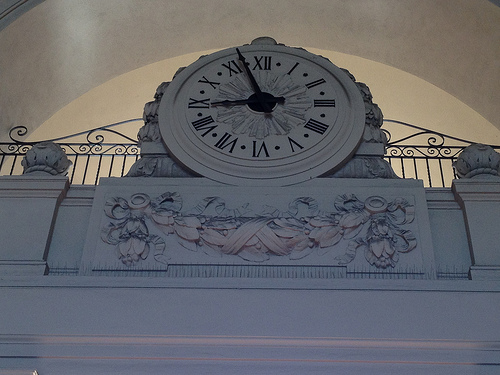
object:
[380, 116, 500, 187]
rail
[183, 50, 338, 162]
face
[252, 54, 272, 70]
roman numeral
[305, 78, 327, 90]
roman numeral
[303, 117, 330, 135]
roman numeral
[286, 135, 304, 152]
roman numeral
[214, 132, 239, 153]
roman numeral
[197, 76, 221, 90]
numeral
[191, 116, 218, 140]
numeral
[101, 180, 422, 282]
painting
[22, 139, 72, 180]
concrete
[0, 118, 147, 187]
rail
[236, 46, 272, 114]
hands